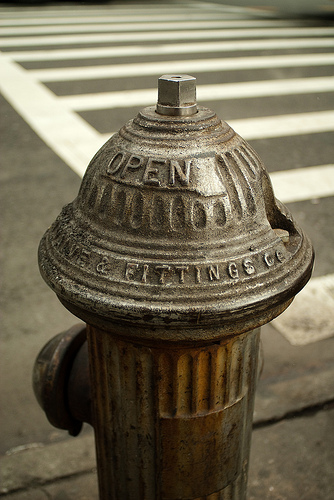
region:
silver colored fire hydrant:
[31, 73, 283, 498]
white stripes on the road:
[1, 6, 332, 346]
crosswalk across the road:
[0, 5, 324, 343]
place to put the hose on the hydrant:
[33, 325, 92, 435]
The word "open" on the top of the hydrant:
[111, 150, 191, 188]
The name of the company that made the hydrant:
[52, 222, 281, 284]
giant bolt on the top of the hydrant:
[160, 72, 197, 114]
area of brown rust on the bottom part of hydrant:
[156, 336, 228, 497]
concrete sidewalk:
[0, 374, 331, 498]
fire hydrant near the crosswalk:
[26, 73, 314, 491]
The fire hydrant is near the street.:
[6, 51, 318, 497]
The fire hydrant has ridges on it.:
[89, 341, 260, 497]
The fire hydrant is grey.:
[29, 56, 310, 496]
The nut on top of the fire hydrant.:
[154, 70, 200, 113]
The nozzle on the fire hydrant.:
[28, 312, 93, 434]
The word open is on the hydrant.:
[104, 144, 195, 192]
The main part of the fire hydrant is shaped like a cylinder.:
[82, 334, 262, 496]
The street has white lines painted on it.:
[3, 4, 331, 345]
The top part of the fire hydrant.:
[32, 68, 312, 310]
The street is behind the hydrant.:
[0, 7, 332, 498]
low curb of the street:
[264, 379, 331, 424]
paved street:
[257, 426, 327, 489]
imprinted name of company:
[58, 245, 289, 280]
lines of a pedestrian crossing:
[23, 19, 148, 94]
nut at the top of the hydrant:
[152, 66, 195, 112]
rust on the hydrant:
[162, 329, 229, 355]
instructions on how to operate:
[103, 141, 219, 198]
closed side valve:
[23, 314, 88, 436]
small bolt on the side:
[262, 218, 291, 243]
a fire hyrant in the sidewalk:
[35, 66, 317, 491]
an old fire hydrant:
[30, 56, 328, 498]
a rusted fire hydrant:
[31, 51, 329, 496]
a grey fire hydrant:
[16, 68, 324, 497]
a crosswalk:
[2, 0, 330, 67]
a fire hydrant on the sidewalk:
[33, 52, 317, 497]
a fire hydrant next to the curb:
[0, 61, 332, 496]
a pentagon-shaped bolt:
[144, 63, 206, 113]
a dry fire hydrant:
[0, 0, 332, 498]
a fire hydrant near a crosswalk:
[0, 39, 329, 496]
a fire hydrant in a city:
[1, 2, 331, 496]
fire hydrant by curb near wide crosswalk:
[11, 5, 330, 493]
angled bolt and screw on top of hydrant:
[152, 68, 193, 113]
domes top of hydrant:
[34, 101, 311, 316]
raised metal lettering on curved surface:
[47, 144, 284, 283]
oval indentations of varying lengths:
[76, 134, 260, 228]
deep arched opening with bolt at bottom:
[255, 151, 299, 252]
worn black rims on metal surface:
[36, 271, 293, 338]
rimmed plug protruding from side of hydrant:
[30, 319, 109, 434]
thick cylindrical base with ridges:
[86, 331, 254, 492]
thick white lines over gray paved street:
[1, 5, 328, 349]